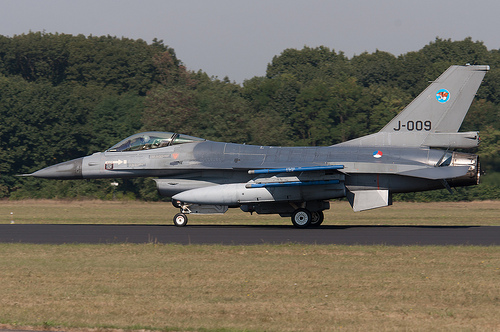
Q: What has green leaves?
A: The trees.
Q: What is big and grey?
A: The jet.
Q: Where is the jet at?
A: On runway.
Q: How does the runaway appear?
A: Appears clear.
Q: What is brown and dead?
A: The grass.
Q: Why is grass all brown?
A: It is dying.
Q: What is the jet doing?
A: Taking off.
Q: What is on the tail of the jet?
A: J-009.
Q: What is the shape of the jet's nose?
A: Pointy.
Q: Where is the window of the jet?
A: The front.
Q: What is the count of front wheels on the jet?
A: 1.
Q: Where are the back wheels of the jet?
A: In the middle.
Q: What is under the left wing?
A: Missile.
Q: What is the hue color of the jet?
A: Gray.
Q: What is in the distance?
A: Trees.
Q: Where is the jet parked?
A: The runway.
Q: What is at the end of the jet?
A: Exhaust/Engine.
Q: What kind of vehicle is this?
A: Airplane.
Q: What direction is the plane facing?
A: Left.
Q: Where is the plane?
A: Green field.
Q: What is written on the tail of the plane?
A: J-009.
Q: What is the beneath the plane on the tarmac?
A: Wheels.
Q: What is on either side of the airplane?
A: Green fields.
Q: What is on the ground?
A: Grass.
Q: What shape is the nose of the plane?
A: Sharp and pointed.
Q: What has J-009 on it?
A: The tail of a jet.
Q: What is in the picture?
A: A fighter jet.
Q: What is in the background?
A: Trees.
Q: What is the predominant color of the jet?
A: Grey.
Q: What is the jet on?
A: A runway.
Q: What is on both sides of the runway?
A: Grass.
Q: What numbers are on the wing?
A: 009.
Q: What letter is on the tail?
A: J.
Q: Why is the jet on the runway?
A: To take off.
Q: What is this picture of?
A: Jet.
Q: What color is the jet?
A: Grey.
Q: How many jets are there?
A: One.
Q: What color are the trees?
A: Green.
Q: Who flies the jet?
A: Pilot.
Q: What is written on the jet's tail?
A: J-009.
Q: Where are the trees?
A: Behind the jet.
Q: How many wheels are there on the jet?
A: Three.